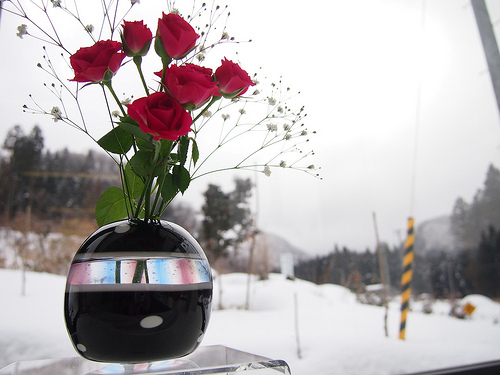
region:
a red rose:
[69, 34, 127, 86]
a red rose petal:
[83, 62, 109, 82]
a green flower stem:
[102, 79, 127, 115]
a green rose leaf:
[86, 179, 135, 231]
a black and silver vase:
[57, 212, 217, 364]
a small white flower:
[263, 117, 283, 136]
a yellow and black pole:
[392, 212, 419, 342]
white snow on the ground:
[1, 266, 498, 373]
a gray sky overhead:
[1, 0, 498, 267]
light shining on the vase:
[135, 306, 171, 333]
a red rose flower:
[61, 31, 128, 86]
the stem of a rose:
[103, 77, 128, 117]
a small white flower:
[256, 161, 276, 181]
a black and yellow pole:
[386, 212, 421, 343]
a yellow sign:
[458, 297, 481, 318]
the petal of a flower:
[81, 63, 111, 83]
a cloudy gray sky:
[1, 0, 499, 263]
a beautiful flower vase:
[0, 0, 330, 365]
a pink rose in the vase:
[104, 88, 192, 230]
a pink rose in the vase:
[62, 32, 124, 134]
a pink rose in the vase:
[113, 12, 156, 70]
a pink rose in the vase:
[157, 58, 222, 110]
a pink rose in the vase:
[213, 50, 260, 111]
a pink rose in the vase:
[156, 1, 207, 66]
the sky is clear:
[0, 0, 496, 227]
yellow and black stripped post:
[395, 205, 415, 357]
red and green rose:
[76, 28, 129, 130]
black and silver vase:
[58, 219, 215, 372]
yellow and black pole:
[381, 201, 428, 373]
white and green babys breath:
[248, 87, 325, 202]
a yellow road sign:
[446, 271, 489, 343]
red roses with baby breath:
[73, 79, 315, 239]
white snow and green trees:
[225, 215, 495, 374]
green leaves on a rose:
[121, 137, 201, 224]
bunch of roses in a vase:
[48, 79, 259, 349]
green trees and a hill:
[1, 129, 74, 267]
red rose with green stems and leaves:
[110, 91, 194, 218]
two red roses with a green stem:
[67, 17, 157, 102]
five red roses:
[67, 12, 257, 220]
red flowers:
[65, 8, 258, 223]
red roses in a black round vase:
[68, 9, 259, 361]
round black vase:
[63, 219, 213, 363]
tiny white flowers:
[198, 106, 323, 179]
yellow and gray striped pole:
[398, 215, 415, 342]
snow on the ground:
[301, 302, 376, 373]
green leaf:
[170, 164, 190, 193]